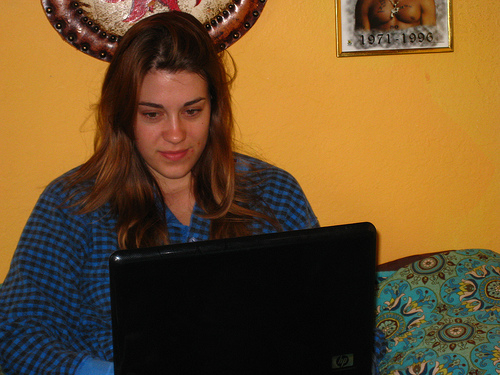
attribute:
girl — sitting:
[1, 9, 334, 373]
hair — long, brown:
[59, 11, 291, 255]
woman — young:
[3, 11, 319, 373]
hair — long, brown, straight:
[38, 9, 285, 251]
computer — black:
[107, 221, 379, 373]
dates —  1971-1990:
[355, 27, 437, 47]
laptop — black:
[109, 223, 376, 374]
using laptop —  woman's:
[82, 46, 382, 309]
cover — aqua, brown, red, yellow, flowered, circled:
[413, 269, 495, 361]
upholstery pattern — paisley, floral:
[376, 244, 498, 368]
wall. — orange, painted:
[290, 92, 423, 156]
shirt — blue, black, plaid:
[13, 157, 351, 346]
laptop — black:
[91, 230, 416, 362]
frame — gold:
[331, 1, 470, 65]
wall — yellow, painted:
[1, 1, 484, 281]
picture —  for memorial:
[335, 0, 454, 57]